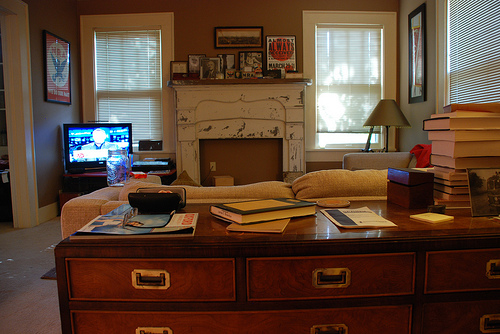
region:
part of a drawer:
[366, 255, 388, 282]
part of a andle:
[316, 270, 341, 314]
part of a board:
[253, 255, 287, 307]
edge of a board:
[227, 209, 260, 246]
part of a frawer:
[303, 233, 343, 308]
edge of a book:
[238, 203, 255, 219]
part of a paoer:
[351, 201, 364, 217]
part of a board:
[272, 274, 299, 318]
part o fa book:
[239, 194, 269, 251]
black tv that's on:
[60, 118, 135, 171]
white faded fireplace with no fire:
[168, 72, 312, 184]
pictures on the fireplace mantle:
[170, 48, 303, 83]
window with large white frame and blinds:
[296, 6, 398, 164]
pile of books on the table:
[421, 95, 498, 205]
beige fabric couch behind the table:
[58, 168, 390, 235]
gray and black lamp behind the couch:
[362, 97, 412, 154]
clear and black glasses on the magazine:
[118, 205, 178, 231]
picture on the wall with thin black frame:
[37, 25, 74, 108]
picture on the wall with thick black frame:
[405, 2, 430, 104]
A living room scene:
[2, 3, 498, 327]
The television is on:
[60, 120, 132, 169]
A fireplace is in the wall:
[167, 80, 309, 182]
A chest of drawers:
[51, 198, 498, 330]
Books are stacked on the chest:
[421, 112, 498, 210]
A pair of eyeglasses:
[120, 204, 182, 229]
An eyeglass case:
[126, 184, 188, 207]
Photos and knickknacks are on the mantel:
[169, 50, 307, 85]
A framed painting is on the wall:
[404, 0, 429, 105]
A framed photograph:
[211, 23, 266, 48]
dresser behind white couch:
[60, 185, 498, 323]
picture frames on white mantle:
[173, 22, 299, 81]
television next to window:
[58, 111, 128, 173]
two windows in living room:
[80, 25, 380, 143]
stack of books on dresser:
[414, 104, 498, 202]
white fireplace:
[169, 82, 306, 182]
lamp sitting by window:
[363, 98, 406, 150]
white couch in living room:
[67, 164, 433, 236]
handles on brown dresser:
[115, 254, 498, 333]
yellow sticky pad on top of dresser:
[410, 199, 456, 220]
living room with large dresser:
[0, 0, 499, 332]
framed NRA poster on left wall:
[41, 27, 73, 104]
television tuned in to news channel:
[62, 122, 132, 171]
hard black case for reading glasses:
[128, 186, 186, 207]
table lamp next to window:
[363, 98, 410, 150]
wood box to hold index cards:
[385, 166, 433, 211]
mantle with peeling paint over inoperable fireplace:
[168, 78, 313, 186]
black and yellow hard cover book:
[208, 194, 318, 224]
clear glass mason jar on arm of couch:
[62, 148, 161, 238]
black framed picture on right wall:
[406, 3, 428, 103]